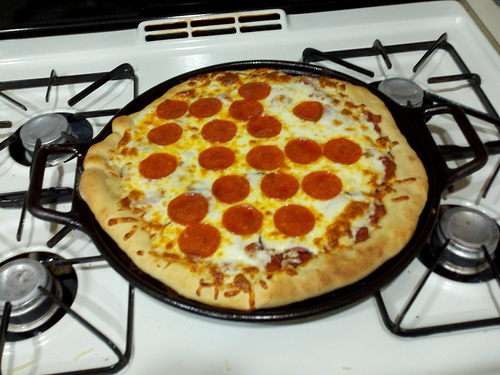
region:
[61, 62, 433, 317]
homemade pizza, i think, not microwave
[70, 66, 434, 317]
crust may be either from a mix, or storebought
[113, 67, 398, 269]
toppings were applied by pizza consumer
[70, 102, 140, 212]
a peri-peculiarly puffy part of crust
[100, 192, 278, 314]
a heavy dribbling of melted cheese this area on crust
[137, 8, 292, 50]
an oven vent, w/ six openings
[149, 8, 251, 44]
oven vent is slightly stained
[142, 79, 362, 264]
pepperoni is unevenly applied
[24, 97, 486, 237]
dual handled pizza pan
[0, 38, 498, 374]
black iron, everything atop the stove but the pizza & the burners+stove themselves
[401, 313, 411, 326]
part of a grill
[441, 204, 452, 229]
part of a burner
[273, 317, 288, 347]
part of a pizza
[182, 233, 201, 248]
edge of a pizza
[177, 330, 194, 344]
part of an oven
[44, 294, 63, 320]
part of a burner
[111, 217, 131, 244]
edge of a pizza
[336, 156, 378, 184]
side of a pizza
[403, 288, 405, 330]
part of a grill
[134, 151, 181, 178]
A piece of pepperoni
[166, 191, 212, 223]
A piece of pepperoni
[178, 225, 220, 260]
A piece of pepperoni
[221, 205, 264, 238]
a piece of pepperoni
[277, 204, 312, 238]
A piece of pepperoni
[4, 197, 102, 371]
Part of gas burner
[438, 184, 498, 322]
Part of gas burner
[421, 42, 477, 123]
Part of gas burner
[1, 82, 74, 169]
Part of gas burner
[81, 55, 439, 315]
Delicious baked pizza pie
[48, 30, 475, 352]
The pizza sitting on top of the stove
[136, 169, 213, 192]
The cheese is the color white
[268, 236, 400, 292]
The crust is the color brown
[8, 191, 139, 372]
The eye of the burner is black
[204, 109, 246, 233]
The pepperoni is the color red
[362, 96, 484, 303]
The iron tray is the color black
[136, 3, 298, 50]
The vent on the stove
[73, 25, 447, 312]
The pizza has been cooked through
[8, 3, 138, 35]
The back of the stove is black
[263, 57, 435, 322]
One half of the pizza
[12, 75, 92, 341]
the stove top is gas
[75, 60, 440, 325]
the pizza has pepperoni on it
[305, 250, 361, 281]
the crust is brown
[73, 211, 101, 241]
the pan is black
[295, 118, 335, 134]
the cheese is white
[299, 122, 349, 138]
the cheese is on the pizza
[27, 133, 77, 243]
the pan has a left handle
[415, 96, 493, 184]
the pan has a right handle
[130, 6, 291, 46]
the stove has a vent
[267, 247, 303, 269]
the sauce is red